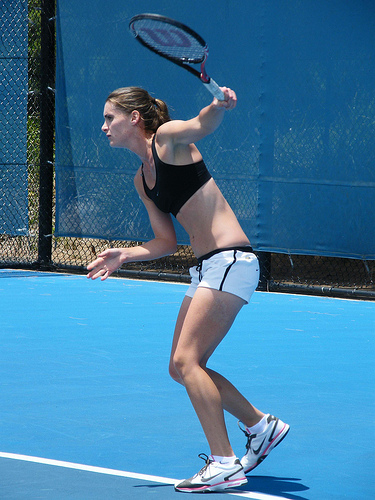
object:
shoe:
[172, 455, 248, 496]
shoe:
[239, 414, 290, 476]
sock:
[208, 455, 237, 467]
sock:
[247, 414, 267, 435]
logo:
[200, 469, 224, 483]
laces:
[196, 451, 209, 469]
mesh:
[133, 19, 205, 61]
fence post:
[35, 1, 57, 267]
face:
[101, 101, 132, 148]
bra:
[141, 134, 212, 219]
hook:
[25, 83, 55, 96]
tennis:
[3, 8, 363, 490]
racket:
[127, 12, 225, 103]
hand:
[212, 85, 238, 110]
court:
[0, 270, 375, 500]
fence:
[0, 0, 375, 302]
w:
[140, 27, 191, 49]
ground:
[0, 268, 375, 500]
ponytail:
[151, 98, 172, 122]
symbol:
[219, 461, 228, 465]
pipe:
[36, 5, 56, 269]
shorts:
[184, 244, 260, 304]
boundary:
[0, 448, 287, 500]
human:
[83, 85, 289, 496]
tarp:
[213, 74, 370, 245]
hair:
[105, 85, 171, 133]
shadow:
[204, 464, 305, 498]